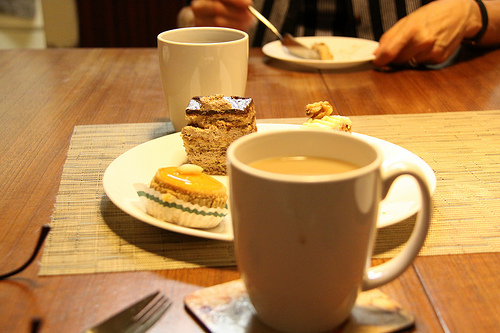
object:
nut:
[306, 101, 333, 119]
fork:
[86, 290, 173, 332]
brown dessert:
[133, 167, 225, 229]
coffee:
[247, 156, 360, 177]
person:
[178, 0, 500, 68]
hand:
[373, 0, 472, 71]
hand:
[179, 0, 256, 33]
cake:
[179, 93, 257, 178]